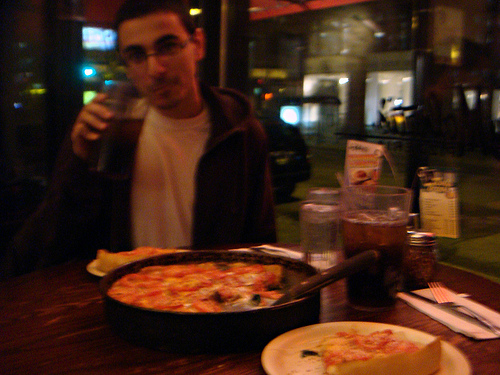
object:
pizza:
[105, 258, 285, 313]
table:
[4, 237, 499, 374]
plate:
[258, 320, 475, 373]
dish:
[101, 262, 323, 327]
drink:
[342, 185, 414, 305]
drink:
[97, 75, 149, 182]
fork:
[398, 280, 500, 334]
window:
[303, 70, 348, 124]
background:
[212, 4, 495, 94]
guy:
[9, 0, 278, 281]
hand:
[72, 92, 115, 154]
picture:
[2, 3, 500, 375]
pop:
[340, 193, 406, 309]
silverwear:
[411, 277, 493, 330]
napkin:
[396, 276, 500, 340]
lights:
[248, 71, 273, 106]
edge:
[150, 245, 183, 251]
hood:
[210, 82, 254, 130]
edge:
[89, 261, 104, 274]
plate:
[87, 250, 131, 274]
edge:
[99, 249, 137, 261]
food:
[96, 246, 190, 275]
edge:
[104, 268, 132, 327]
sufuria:
[86, 251, 322, 327]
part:
[83, 260, 102, 277]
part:
[5, 277, 48, 361]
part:
[328, 248, 387, 272]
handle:
[269, 249, 378, 310]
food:
[315, 326, 441, 374]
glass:
[91, 79, 152, 176]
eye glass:
[117, 34, 195, 67]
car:
[248, 110, 312, 204]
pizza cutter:
[260, 242, 384, 309]